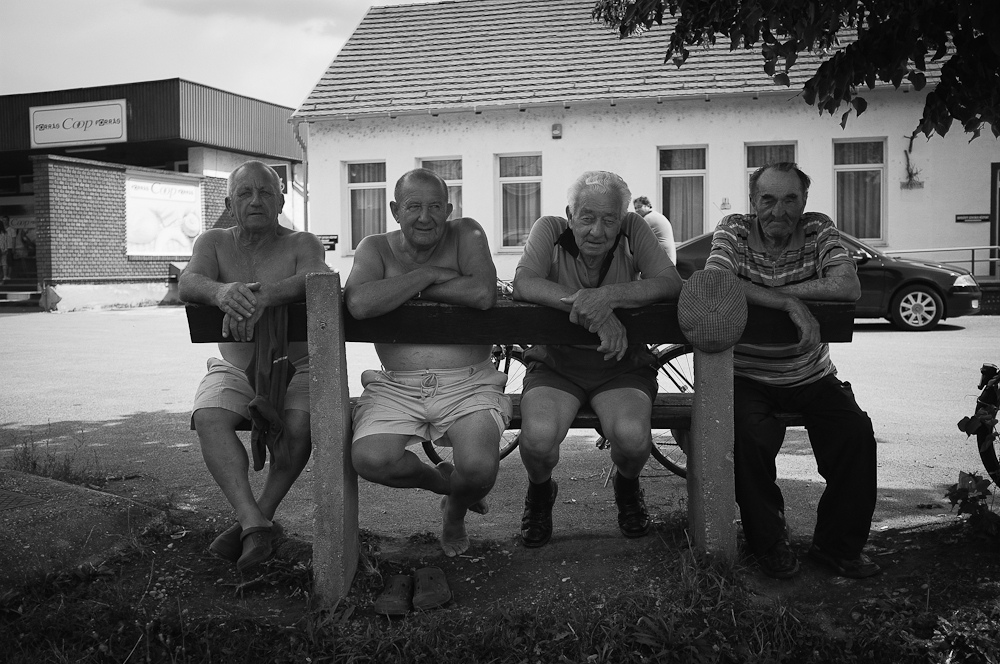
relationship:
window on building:
[338, 150, 386, 251] [311, 0, 996, 278]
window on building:
[421, 154, 462, 219] [311, 0, 996, 278]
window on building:
[489, 144, 543, 245] [311, 0, 996, 278]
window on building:
[658, 144, 706, 248] [311, 0, 996, 278]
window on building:
[741, 146, 799, 200] [311, 0, 996, 278]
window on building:
[832, 134, 882, 249] [311, 0, 996, 278]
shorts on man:
[186, 347, 320, 442] [186, 169, 323, 591]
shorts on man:
[339, 364, 514, 438] [339, 170, 514, 555]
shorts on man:
[522, 336, 660, 394] [496, 176, 678, 544]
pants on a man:
[734, 370, 886, 554] [706, 152, 886, 554]